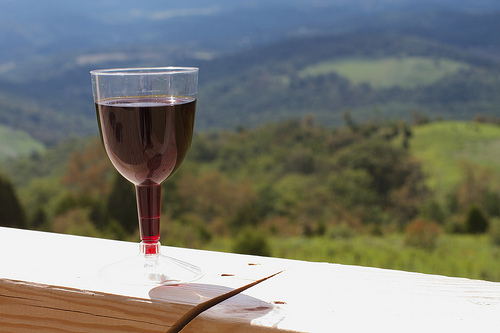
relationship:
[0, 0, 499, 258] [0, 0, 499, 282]
trees in background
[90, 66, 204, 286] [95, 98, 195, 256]
glass full of wine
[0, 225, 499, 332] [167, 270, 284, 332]
sill has crack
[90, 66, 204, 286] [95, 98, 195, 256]
glass of wine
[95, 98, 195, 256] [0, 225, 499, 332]
wine on top of sill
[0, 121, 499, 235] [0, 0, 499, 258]
hill has trees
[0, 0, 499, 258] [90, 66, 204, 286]
trees are behind glass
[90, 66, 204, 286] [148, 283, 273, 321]
glass has a shadow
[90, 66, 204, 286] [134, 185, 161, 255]
glass has handle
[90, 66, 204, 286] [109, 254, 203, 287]
glass has base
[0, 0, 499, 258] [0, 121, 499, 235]
trees are on hill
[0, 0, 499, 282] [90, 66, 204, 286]
hills are behind glass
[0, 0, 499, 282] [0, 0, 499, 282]
background has grass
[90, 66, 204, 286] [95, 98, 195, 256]
glass has wine